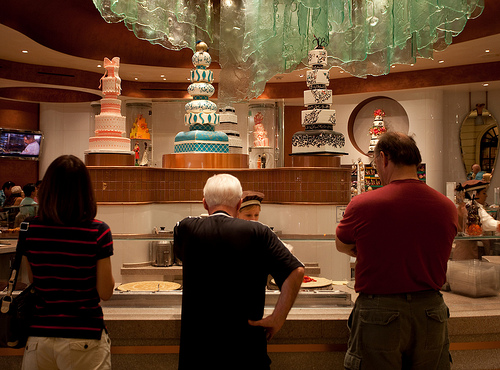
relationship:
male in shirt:
[329, 127, 462, 368] [334, 177, 459, 292]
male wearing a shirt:
[329, 127, 462, 368] [333, 186, 465, 300]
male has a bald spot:
[329, 127, 462, 368] [393, 126, 413, 146]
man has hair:
[169, 172, 306, 367] [201, 166, 244, 206]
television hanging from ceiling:
[0, 126, 45, 161] [1, 3, 499, 143]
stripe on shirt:
[95, 225, 109, 243] [18, 216, 113, 342]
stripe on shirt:
[22, 221, 100, 233] [18, 216, 113, 342]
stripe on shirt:
[19, 235, 99, 247] [18, 216, 113, 342]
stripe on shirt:
[25, 248, 102, 259] [18, 216, 113, 342]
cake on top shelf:
[171, 39, 231, 152] [155, 148, 249, 173]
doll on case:
[127, 112, 152, 140] [125, 99, 155, 167]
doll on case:
[127, 121, 137, 140] [125, 99, 155, 167]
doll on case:
[140, 142, 154, 166] [125, 99, 155, 167]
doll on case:
[130, 141, 141, 163] [125, 99, 155, 167]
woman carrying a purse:
[11, 149, 115, 370] [0, 217, 32, 349]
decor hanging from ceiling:
[93, 0, 488, 75] [2, 2, 497, 117]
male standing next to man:
[329, 127, 462, 368] [169, 172, 306, 370]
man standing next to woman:
[169, 172, 306, 370] [11, 149, 115, 370]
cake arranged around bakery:
[291, 48, 346, 153] [0, 0, 500, 370]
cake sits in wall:
[367, 109, 387, 152] [326, 86, 444, 206]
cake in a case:
[126, 108, 151, 142] [128, 99, 155, 168]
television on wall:
[0, 126, 45, 161] [0, 99, 37, 196]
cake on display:
[291, 43, 345, 159] [78, 161, 348, 283]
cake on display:
[171, 39, 231, 152] [78, 161, 348, 283]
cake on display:
[84, 56, 132, 151] [78, 161, 348, 283]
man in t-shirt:
[169, 172, 306, 367] [164, 206, 306, 365]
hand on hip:
[248, 312, 285, 339] [244, 311, 269, 368]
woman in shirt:
[11, 149, 115, 370] [35, 220, 99, 335]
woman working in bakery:
[11, 131, 128, 368] [30, 144, 493, 354]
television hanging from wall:
[0, 126, 45, 161] [0, 106, 45, 202]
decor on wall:
[88, 0, 489, 111] [259, 80, 493, 153]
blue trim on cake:
[169, 131, 196, 155] [170, 37, 226, 153]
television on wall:
[0, 126, 45, 161] [14, 92, 79, 185]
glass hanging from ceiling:
[217, 4, 461, 79] [2, 2, 497, 117]